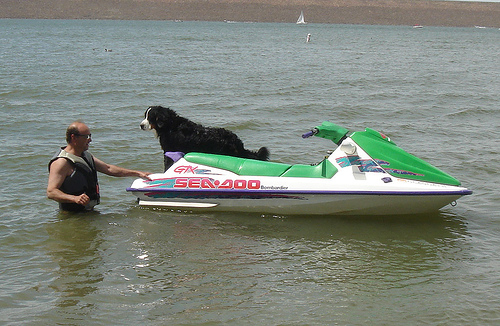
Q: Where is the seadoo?
A: In water.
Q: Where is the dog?
A: On seadoo.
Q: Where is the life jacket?
A: On man.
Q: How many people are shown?
A: 1.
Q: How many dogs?
A: 1.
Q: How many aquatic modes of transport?
A: 2.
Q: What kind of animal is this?
A: Dog.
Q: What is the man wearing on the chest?
A: Life vest.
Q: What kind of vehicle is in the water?
A: Boat.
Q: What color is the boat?
A: Green and white.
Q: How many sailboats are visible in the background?
A: One.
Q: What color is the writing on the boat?
A: Red and blue.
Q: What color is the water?
A: Brown.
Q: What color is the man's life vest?
A: Grey.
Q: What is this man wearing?
A: A life vest.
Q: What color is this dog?
A: Black and white.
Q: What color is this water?
A: Brown.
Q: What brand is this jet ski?
A: Sea-Doo.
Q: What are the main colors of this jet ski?
A: Green and white.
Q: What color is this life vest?
A: Grey.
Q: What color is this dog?
A: Black and white.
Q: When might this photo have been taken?
A: Morning or afternoon.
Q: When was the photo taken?
A: Afternoon.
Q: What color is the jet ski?
A: Green and white.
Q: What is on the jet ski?
A: A dog.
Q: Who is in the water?
A: A man.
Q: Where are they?
A: In water.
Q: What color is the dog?
A: Black and white.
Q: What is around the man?
A: Life vest.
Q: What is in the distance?
A: A boat.